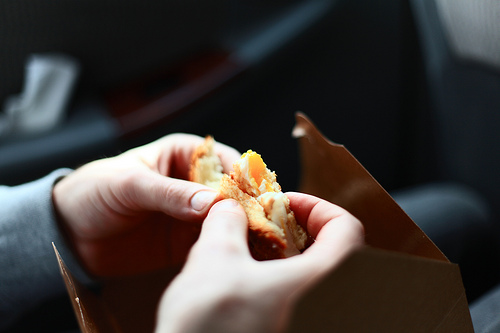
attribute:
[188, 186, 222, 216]
thum nail — white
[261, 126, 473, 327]
box — brown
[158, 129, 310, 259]
sandwich — brown, orange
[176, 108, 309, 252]
food — brown, white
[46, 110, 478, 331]
box — cardboard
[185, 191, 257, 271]
thumb — white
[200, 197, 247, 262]
thumb — white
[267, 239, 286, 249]
seed — small, white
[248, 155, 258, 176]
cheese — yellow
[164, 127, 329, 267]
sandwich — yummy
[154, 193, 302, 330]
finger — white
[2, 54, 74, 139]
tissue — white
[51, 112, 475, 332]
bag — brown, paper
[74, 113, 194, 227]
hand — white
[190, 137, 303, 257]
bread — edible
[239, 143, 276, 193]
substance — yellow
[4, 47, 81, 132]
cloth — White 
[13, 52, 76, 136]
tissue — white